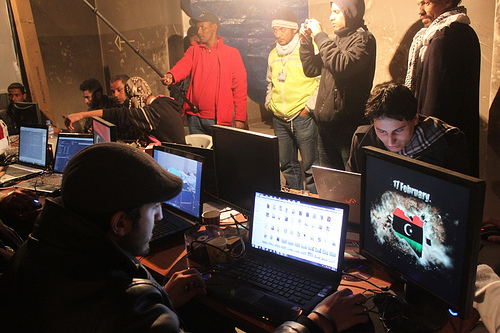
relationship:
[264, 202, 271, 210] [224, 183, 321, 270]
icon on screen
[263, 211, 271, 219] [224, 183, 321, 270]
icon on screen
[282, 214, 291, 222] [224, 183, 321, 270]
icon on screen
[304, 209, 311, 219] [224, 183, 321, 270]
icon on screen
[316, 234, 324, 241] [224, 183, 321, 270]
icon on screen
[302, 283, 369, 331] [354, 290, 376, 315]
hand on mouse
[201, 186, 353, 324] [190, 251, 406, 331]
laptop on table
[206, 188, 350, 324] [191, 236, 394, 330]
laptop on table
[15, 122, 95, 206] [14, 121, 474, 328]
laptop on table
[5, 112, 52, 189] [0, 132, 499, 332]
laptop on table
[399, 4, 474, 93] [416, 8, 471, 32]
scarf around neck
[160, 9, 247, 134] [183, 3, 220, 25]
man wearing blue hat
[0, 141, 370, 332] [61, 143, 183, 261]
man has head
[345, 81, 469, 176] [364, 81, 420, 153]
man has head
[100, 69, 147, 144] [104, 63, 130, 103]
person has head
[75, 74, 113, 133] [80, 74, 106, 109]
person has head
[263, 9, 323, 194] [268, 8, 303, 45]
man has head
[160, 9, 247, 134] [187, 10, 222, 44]
man has head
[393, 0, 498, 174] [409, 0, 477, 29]
person has head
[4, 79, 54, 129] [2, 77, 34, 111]
person has head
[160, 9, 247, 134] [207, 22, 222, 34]
man has ear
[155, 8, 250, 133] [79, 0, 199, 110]
man holding boom mic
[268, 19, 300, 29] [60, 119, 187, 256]
band around head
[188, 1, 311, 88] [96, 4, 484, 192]
artwork on wall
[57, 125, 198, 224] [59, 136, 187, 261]
dark hat on head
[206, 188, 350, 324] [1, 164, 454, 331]
laptop on table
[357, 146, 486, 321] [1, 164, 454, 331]
monitor on table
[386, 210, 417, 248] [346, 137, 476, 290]
flag on screen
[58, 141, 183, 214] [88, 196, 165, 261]
dark hat on head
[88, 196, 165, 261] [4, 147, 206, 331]
head of man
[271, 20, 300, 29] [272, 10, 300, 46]
band on head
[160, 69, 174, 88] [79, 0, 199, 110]
hand on boom mic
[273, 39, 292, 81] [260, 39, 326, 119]
chain on shirt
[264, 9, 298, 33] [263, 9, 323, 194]
hat on man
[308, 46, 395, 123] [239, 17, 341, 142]
sweater on man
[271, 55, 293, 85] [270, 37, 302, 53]
hanging badge on neck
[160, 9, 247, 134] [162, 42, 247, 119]
man wears red jacket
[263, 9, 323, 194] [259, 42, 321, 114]
man wears shirt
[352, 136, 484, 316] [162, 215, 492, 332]
monitor on table